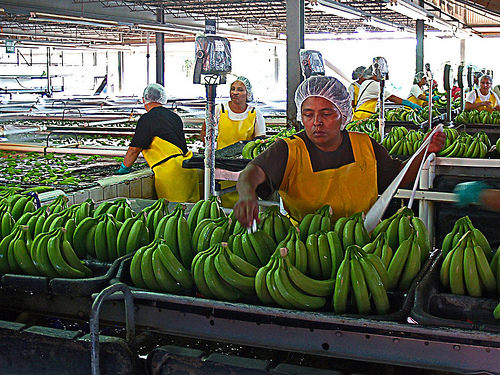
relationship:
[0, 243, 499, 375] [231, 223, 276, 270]
cart has bananas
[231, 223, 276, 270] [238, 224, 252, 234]
bananas have a stem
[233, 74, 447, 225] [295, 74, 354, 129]
man wearing a hairnet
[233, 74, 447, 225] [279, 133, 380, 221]
man wearing an apron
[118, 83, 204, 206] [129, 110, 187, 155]
man wearing a shirt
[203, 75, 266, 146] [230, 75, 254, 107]
woman has a head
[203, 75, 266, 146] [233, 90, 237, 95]
woman has a nose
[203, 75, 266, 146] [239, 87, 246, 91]
woman has an eye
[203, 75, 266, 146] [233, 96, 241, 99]
woman has a mouth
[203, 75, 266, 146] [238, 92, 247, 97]
woman has a cheek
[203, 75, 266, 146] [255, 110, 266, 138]
woman has an arm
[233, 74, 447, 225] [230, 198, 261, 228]
woman has a hand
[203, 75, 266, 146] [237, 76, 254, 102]
woman wearing a bag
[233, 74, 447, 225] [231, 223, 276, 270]
woman by bananas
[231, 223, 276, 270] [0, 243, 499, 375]
bananas are on stand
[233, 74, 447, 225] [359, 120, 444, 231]
woman has a bag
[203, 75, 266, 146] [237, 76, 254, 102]
woman wearing a net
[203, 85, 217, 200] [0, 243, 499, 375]
pole by stand